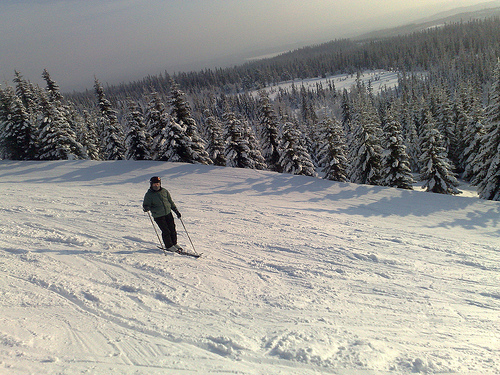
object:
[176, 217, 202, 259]
stick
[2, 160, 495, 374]
snow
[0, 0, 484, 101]
skies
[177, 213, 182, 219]
hand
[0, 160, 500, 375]
field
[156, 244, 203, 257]
snow skis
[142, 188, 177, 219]
coat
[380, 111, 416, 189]
tree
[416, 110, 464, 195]
tree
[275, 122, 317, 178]
tree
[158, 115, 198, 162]
tree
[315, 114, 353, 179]
tree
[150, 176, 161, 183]
hat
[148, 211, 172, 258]
stick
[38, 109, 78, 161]
snow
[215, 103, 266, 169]
tree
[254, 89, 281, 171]
tree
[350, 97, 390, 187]
tree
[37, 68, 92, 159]
tree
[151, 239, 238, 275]
ski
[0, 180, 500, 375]
slope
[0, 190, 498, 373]
tracks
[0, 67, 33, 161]
trees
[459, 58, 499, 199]
trees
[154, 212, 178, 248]
pants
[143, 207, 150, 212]
hand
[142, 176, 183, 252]
athlete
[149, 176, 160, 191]
head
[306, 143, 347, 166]
snow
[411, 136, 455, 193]
snow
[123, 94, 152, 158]
trees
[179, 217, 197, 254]
poles